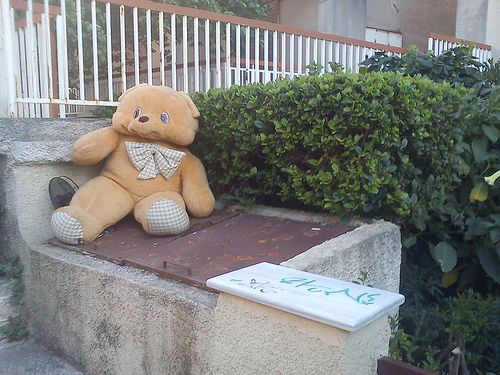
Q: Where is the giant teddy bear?
A: Outside the house.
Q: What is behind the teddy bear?
A: A fence.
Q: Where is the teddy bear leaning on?
A: Concrete wall near stairs.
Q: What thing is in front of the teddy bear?
A: Rectangular tile.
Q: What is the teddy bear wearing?
A: A bow tie.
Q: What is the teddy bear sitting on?
A: Metal door.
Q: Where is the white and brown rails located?
A: Behind the teddy bear.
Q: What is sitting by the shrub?
A: Teddy Bear.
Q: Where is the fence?
A: Around porch.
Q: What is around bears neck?
A: Bow.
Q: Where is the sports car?
A: No sports car.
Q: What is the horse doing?
A: No horse.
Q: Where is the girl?
A: No girl.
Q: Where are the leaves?
A: On bushes.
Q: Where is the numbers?
A: No numbers.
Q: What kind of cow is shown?
A: No cow.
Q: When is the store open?
A: No store.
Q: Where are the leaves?
A: On plant.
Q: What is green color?
A: Plant.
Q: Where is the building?
A: In background.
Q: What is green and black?
A: Graffiti.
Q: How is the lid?
A: Rusty.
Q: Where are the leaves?
A: On bush.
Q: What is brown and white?
A: Fence.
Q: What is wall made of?
A: Concrete.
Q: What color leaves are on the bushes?
A: Green.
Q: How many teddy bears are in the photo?
A: One.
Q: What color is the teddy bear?
A: Brown.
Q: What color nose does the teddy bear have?
A: Brown.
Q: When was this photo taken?
A: Daytime.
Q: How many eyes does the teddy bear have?
A: Two.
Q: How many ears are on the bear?
A: Two.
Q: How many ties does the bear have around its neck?
A: One.